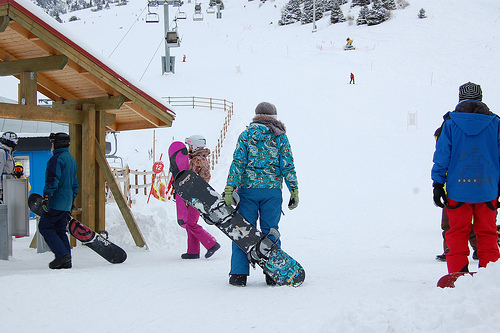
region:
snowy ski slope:
[196, 28, 416, 330]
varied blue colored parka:
[228, 117, 300, 196]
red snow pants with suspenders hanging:
[436, 198, 497, 277]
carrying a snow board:
[173, 166, 306, 291]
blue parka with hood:
[431, 101, 498, 208]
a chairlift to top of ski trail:
[93, 0, 239, 86]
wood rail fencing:
[161, 90, 236, 161]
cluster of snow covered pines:
[266, 0, 421, 27]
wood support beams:
[1, 94, 138, 251]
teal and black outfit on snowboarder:
[26, 128, 86, 275]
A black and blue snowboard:
[173, 164, 308, 287]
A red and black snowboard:
[26, 193, 126, 267]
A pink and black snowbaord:
[168, 139, 193, 227]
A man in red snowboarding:
[349, 71, 357, 86]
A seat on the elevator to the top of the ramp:
[163, 29, 186, 50]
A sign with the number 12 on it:
[145, 152, 165, 202]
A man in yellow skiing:
[339, 33, 357, 51]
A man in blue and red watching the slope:
[431, 78, 499, 288]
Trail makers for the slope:
[199, 19, 447, 86]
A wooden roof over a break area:
[1, 1, 176, 134]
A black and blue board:
[172, 167, 307, 287]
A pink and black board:
[168, 137, 194, 227]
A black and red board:
[26, 189, 128, 265]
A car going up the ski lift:
[161, 24, 185, 51]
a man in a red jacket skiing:
[347, 69, 357, 87]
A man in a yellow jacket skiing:
[338, 35, 358, 50]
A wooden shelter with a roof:
[0, 0, 182, 247]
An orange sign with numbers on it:
[148, 149, 166, 201]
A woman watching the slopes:
[220, 101, 303, 285]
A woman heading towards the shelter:
[165, 134, 225, 259]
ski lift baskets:
[142, 0, 227, 77]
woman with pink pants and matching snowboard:
[167, 133, 222, 262]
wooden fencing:
[106, 94, 236, 197]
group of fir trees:
[276, 1, 410, 28]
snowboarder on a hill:
[341, 36, 358, 52]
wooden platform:
[0, 0, 177, 256]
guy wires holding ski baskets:
[103, 1, 180, 83]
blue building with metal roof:
[0, 95, 71, 221]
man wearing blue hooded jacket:
[428, 81, 498, 276]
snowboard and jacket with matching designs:
[171, 120, 308, 290]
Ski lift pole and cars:
[136, 4, 202, 76]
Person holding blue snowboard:
[172, 101, 308, 285]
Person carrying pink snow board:
[167, 135, 219, 266]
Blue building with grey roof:
[5, 118, 75, 223]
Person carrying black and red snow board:
[27, 131, 129, 270]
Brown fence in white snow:
[177, 92, 235, 133]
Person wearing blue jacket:
[429, 102, 495, 206]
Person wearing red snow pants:
[441, 198, 498, 270]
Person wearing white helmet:
[183, 131, 207, 152]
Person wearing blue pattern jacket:
[220, 115, 301, 192]